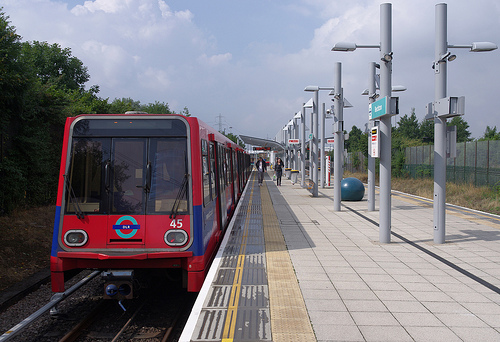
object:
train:
[46, 110, 253, 318]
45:
[169, 218, 183, 229]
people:
[255, 156, 267, 187]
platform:
[178, 163, 500, 342]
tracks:
[58, 285, 186, 342]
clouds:
[69, 0, 196, 44]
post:
[376, 2, 393, 243]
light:
[331, 42, 384, 52]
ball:
[340, 177, 365, 202]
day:
[0, 0, 497, 341]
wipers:
[169, 174, 191, 219]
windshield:
[63, 117, 190, 215]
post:
[332, 61, 346, 212]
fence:
[405, 139, 500, 188]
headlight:
[163, 229, 189, 247]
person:
[274, 158, 285, 187]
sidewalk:
[234, 168, 500, 342]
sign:
[368, 96, 391, 122]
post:
[429, 2, 451, 244]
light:
[304, 85, 335, 92]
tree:
[0, 9, 39, 217]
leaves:
[33, 40, 36, 42]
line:
[219, 168, 256, 342]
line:
[175, 166, 254, 342]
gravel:
[15, 298, 42, 308]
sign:
[370, 125, 382, 158]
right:
[447, 0, 498, 342]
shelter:
[239, 134, 285, 151]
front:
[48, 113, 206, 292]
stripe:
[254, 179, 322, 342]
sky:
[0, 0, 500, 153]